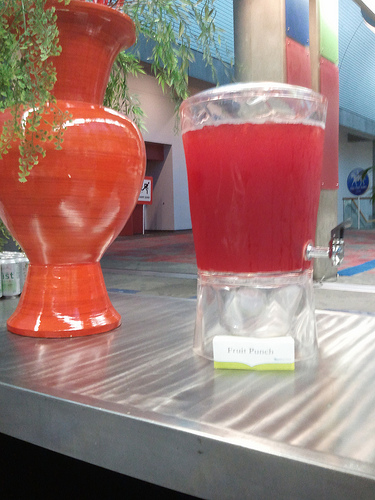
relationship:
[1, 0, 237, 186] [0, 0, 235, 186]
leaves on plant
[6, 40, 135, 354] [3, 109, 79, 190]
planter with plant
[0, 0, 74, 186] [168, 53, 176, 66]
plant has leaf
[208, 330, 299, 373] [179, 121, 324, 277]
card for drinks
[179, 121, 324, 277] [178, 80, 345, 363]
drinks in container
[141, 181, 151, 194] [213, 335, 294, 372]
figure on card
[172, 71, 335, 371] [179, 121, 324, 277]
container has drinks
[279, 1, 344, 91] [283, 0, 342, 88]
retangles on column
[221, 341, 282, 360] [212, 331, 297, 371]
fruit punch on sign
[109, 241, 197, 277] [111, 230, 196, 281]
carpet on ground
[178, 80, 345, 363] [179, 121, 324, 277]
container has drinks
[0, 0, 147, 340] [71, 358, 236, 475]
pot on table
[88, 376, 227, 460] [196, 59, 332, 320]
counter with drinks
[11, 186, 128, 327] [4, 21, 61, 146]
pot with plant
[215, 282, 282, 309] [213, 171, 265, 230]
glass of punch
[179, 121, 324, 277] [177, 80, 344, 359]
drinks in glass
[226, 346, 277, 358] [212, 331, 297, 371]
fruit punch printed on sign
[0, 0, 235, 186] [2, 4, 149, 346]
plant in vase